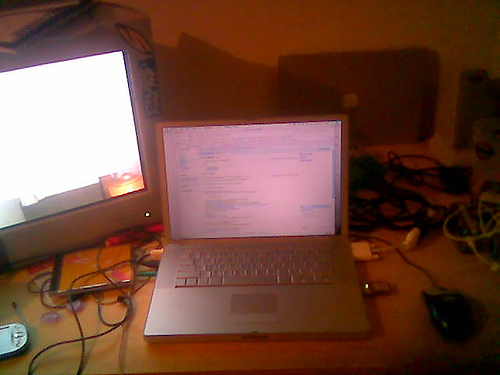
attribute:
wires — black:
[348, 156, 491, 225]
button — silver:
[275, 270, 295, 288]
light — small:
[356, 279, 370, 294]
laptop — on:
[147, 119, 384, 346]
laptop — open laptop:
[213, 107, 379, 256]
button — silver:
[171, 278, 186, 290]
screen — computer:
[148, 117, 350, 237]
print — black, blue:
[182, 143, 314, 218]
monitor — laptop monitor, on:
[159, 119, 344, 251]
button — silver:
[201, 252, 215, 266]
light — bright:
[0, 77, 132, 173]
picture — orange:
[84, 166, 149, 190]